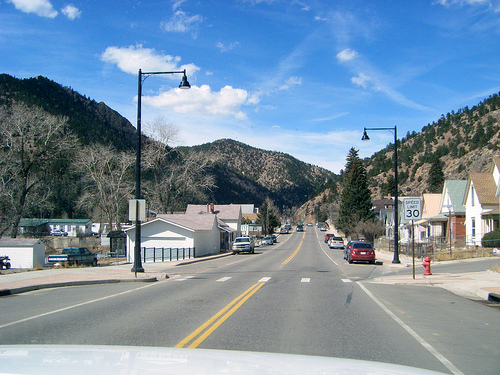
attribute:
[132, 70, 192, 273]
street light — tall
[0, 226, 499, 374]
road — paved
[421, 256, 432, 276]
fire hydrant — red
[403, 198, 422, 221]
sign — speed limit, white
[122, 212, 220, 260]
house — white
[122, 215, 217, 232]
roof — brown, slanted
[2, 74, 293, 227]
mountain — big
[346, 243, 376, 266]
car — red, parked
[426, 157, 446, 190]
tree — evergreen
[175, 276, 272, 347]
line — white, painted, double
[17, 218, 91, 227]
roof — green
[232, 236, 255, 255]
vehicle — parked, white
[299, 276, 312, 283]
line — white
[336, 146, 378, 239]
tree — tall, large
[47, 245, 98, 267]
pickup truck — blue, dark, white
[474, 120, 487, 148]
tree — evergreen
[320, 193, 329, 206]
tree — evergreen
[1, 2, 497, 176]
sky — cloudy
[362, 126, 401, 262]
street light — tall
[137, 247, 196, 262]
fence — metal, long